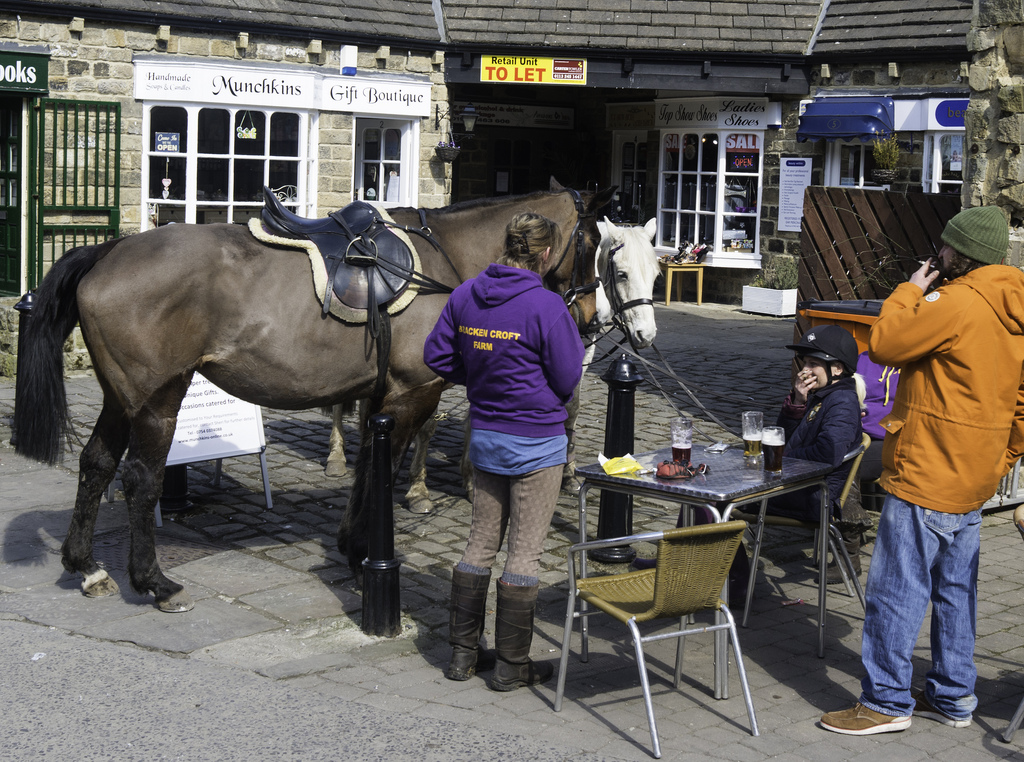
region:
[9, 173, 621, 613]
a brown horse wearing a saddle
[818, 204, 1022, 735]
person holding a cigarette near their mouth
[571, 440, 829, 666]
a square metal table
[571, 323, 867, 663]
girl seated in chair behind table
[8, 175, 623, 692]
female standing in front of brown horse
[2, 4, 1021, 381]
a brick and stone building with signs on it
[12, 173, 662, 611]
white horse standing close to brown horse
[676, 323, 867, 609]
woman covering her mouth with her hand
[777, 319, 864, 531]
Kid with a hat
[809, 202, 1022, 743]
Man with an orange sweater and blue jeans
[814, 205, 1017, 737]
Man smoking a cigarette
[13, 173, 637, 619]
Large brown horse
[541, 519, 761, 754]
Small brown chair with metal legs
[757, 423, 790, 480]
Drink on top of a table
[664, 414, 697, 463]
Drink on top of a table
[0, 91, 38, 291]
A green door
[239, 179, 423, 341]
an English saddle is on the horse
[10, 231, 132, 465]
the horse has a black tail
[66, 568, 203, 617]
horseshoes are on the horse's hooves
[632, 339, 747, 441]
the reins are in front of the horses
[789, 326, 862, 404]
the girl has a black riding helmet on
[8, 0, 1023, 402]
shops surround the cobbled square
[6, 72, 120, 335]
a green iron gate is open at the doorway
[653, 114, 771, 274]
the shop has a bay window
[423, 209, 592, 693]
woman wearing purple sweatshirt and brown boots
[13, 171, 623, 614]
brown horse is wearing a saddle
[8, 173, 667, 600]
white horse standing in front of brown horse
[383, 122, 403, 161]
glass is clean and clear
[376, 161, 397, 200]
glass is clean and clear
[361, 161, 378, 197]
glass is clean and clear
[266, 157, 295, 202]
glass is clean and clear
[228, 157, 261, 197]
glass is clean and clear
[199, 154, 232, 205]
glass is clean and clear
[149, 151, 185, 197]
glass is clean and clear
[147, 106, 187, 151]
glass is clean and clear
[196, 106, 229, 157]
glass is clean and clear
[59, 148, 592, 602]
brown horse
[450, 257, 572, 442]
purple jacket worn by young woman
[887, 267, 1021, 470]
orange jacket worn by man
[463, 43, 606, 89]
red and yellow hanging sign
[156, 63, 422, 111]
black logo on white board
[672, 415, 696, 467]
brown dark beer in clear glass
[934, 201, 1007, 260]
Green knit hat worn by a man.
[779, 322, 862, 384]
Black hat worn by a woman.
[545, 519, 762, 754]
Empty wicker and metal chair.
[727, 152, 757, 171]
Red and blue 'Open' sign in a window.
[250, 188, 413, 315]
Black leather saddle on a horse.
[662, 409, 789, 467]
Three glasses on a square table.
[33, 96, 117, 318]
Green painted metal security door.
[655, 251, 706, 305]
Light brown wooden table in front of window.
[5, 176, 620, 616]
Brown horse with black tail.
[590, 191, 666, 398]
The white head of a horse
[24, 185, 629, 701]
A black and brown horse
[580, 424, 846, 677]
A small square table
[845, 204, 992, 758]
A person smoking a cigarette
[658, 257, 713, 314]
A brown wooden table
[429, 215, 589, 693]
A person wearing a purple hoodie with yellow lettering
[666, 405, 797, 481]
Glass cups resting on top of a table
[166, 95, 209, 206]
a window on the building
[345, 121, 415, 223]
a window on the building